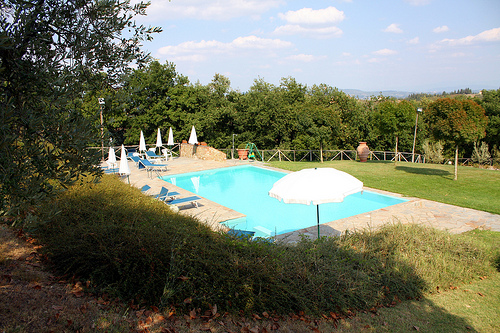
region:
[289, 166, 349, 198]
open white umbrella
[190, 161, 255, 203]
pool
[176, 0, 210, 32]
white clouds in blue sky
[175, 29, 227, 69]
white clouds in blue sky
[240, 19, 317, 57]
white clouds in blue sky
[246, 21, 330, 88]
white clouds in blue sky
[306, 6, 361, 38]
white clouds in blue sky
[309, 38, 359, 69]
white clouds in blue sky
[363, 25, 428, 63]
white clouds in blue sky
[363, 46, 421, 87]
white clouds in blue sky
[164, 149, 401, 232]
rectangular shaped pool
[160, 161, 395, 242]
blue water of pool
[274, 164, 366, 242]
white umbrella on black pole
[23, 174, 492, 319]
bushes around the pool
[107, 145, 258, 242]
blue chairs by the pool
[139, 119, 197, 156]
four umbrellas at other end of pool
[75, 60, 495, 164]
line of trees on back side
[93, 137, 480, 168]
wood fencing in front of trees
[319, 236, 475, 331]
shadows on the grass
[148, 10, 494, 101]
white clouds in the blue sky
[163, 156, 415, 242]
rectangular swimming pool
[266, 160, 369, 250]
open white umbrella outside the pool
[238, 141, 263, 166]
green swing set near the pool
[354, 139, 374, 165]
large vase in the yard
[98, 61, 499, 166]
line of trees outside the fence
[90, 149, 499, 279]
patio outside the pool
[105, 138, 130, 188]
group of two closed umbrellas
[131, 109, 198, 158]
group of four closed umbrellas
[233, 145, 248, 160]
plant potter near the swing set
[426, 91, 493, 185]
tree in the yard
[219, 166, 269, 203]
blue swimming pool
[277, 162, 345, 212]
umbrella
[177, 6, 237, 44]
white clouds in blue sky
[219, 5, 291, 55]
white clouds in blue sky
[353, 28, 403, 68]
white clouds in blue sky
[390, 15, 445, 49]
white clouds in blue sky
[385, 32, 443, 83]
white clouds in blue sky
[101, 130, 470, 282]
A pool in a backyard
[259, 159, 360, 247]
An umbrella near a pool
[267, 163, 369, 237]
An open umbrella near a pool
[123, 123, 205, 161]
Closed umbrellas by a pool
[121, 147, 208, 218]
Blue chairs by a pool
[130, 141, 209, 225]
Lounge chairs by a pool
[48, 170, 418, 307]
Shrubs near a pool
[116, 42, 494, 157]
Trees beyond the yard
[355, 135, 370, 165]
A large planter in the yard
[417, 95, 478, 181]
A tree in the yard